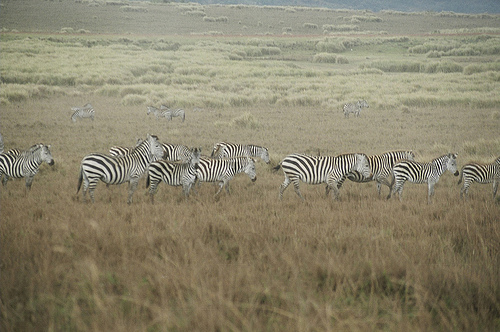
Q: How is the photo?
A: Clear.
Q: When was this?
A: Daytime.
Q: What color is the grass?
A: Pale yellow.